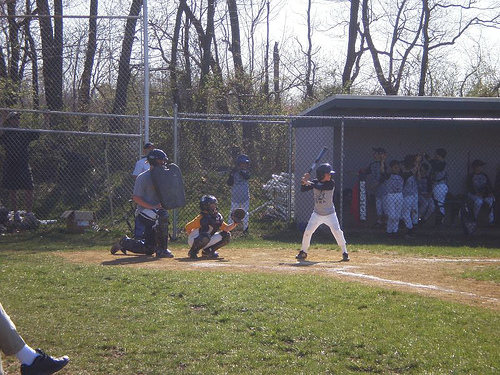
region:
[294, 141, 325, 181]
a black baseball bat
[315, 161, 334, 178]
a black baseball helmet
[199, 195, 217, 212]
a black baseball helmet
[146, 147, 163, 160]
a black baseball helmet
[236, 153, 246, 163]
a black baseball helmet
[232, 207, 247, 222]
a brown baseball glove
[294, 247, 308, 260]
a black baseball cleat of batter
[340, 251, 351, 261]
a black baseball cleat of batter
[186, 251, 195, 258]
a black baseball cleat of catcher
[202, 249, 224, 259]
a black baseball cleat of catcher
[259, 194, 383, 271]
the pants is white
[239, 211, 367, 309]
the pants is white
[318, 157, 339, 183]
the head of a boy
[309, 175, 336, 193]
the arm of a boy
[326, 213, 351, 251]
the leg of a boy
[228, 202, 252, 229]
a black catcher's mitt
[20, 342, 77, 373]
a black shoe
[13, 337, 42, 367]
a white sock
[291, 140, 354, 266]
a boy holding a bat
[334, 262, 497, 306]
a white line on the dirt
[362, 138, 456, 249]
the boys are cheering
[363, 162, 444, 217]
the boys are cheering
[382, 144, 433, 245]
the boys are cheering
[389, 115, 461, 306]
the boys are cheering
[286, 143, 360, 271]
young baseball player at bat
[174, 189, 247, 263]
young catcher waiting for pitch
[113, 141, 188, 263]
kneeling umpire waiting for pitch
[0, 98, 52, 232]
man in dark clothes leaning on fence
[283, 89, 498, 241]
long gray dugout building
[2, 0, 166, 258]
high fence behind home plate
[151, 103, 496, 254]
metal fence around baseball field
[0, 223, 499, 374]
green grassy baseball field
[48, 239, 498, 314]
infield dirt on baseball field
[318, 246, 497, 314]
long chalk lines on baseball field